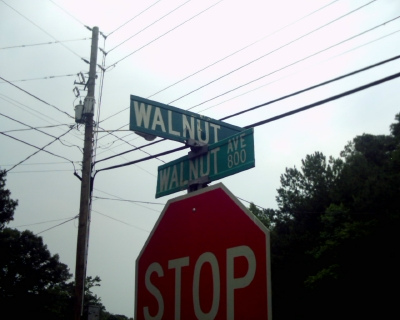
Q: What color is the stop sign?
A: Red.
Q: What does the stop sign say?
A: Stop.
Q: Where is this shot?
A: Walnut and walnut intersection.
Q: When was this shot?
A: Daytime.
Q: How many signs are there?
A: 3.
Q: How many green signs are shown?
A: 2.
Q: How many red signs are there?
A: 1.